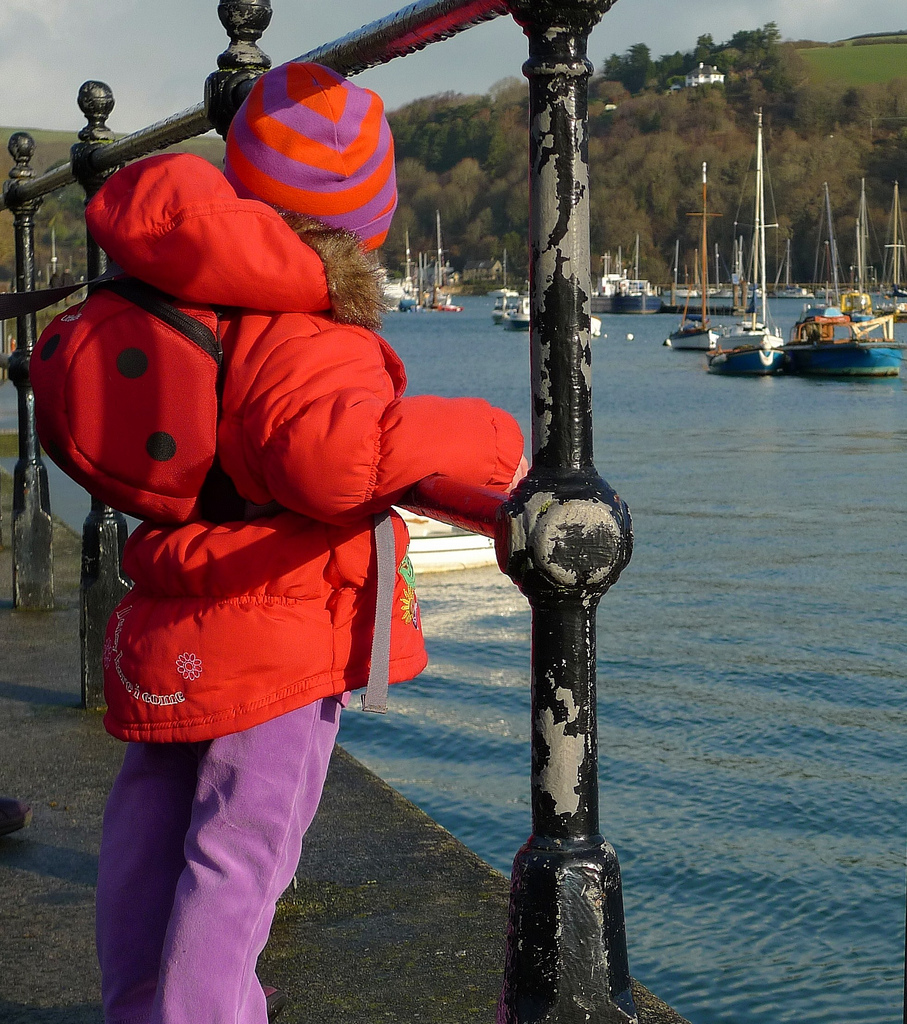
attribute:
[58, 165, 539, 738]
jacket — red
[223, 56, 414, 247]
hat — red, purple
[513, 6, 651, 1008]
metal railing — metal 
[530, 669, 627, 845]
chipped paint — chipped 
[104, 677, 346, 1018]
purple pants — purple 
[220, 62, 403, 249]
knit cap — striped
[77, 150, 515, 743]
jacket — red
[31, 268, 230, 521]
backpack — red, black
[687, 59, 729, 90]
house — black, white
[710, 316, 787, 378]
boat — white, blue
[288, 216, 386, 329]
fur — brown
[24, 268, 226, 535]
backpack — black, red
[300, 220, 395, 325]
fur — brown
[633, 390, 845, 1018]
water — dark blue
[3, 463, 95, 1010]
walkway — concrete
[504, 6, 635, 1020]
railing — black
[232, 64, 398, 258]
hat — red, purple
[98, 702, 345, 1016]
pants — purple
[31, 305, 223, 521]
backpack — red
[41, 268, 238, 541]
backpack — red, black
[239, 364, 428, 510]
coat — large, puffy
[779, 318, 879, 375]
sailboats — blue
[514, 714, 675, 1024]
railing — black